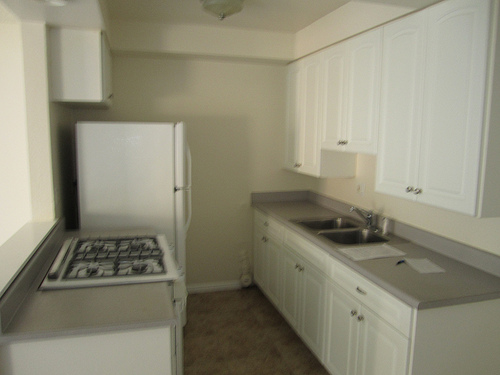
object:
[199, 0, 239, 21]
light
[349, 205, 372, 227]
faucet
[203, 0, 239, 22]
lamp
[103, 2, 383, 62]
ceiling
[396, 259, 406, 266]
pen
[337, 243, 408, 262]
paper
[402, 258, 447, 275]
paper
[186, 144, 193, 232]
handle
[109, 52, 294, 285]
beige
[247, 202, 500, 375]
counter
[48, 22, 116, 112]
white cabinets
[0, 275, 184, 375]
white cabinets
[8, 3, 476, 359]
kitchen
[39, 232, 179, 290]
burners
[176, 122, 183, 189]
door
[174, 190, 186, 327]
door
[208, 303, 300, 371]
floor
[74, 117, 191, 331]
efridgerator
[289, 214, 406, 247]
stainless steel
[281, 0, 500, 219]
cabinets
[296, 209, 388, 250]
sink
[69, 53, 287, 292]
wall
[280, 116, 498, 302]
wall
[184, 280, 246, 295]
molding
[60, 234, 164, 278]
range